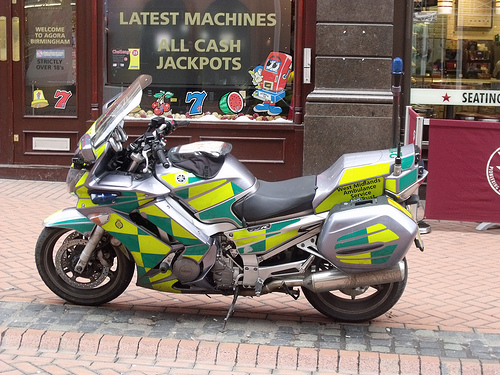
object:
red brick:
[177, 339, 198, 368]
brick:
[51, 328, 88, 359]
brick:
[35, 325, 64, 355]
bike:
[29, 71, 432, 334]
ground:
[1, 179, 498, 374]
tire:
[34, 228, 135, 306]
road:
[0, 178, 500, 373]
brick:
[96, 332, 120, 361]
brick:
[450, 259, 470, 267]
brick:
[163, 305, 200, 318]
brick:
[296, 347, 320, 371]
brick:
[440, 315, 465, 326]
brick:
[419, 355, 441, 374]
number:
[184, 89, 209, 117]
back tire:
[302, 250, 409, 324]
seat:
[230, 171, 322, 228]